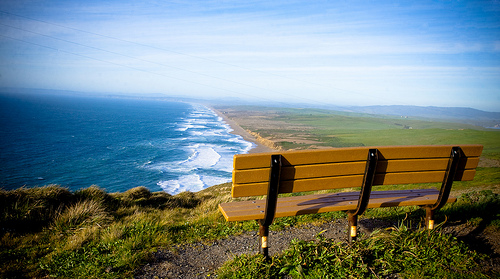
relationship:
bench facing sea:
[218, 146, 483, 259] [1, 87, 252, 196]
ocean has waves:
[0, 91, 251, 197] [190, 106, 249, 192]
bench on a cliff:
[218, 146, 483, 259] [0, 165, 496, 278]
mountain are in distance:
[326, 104, 498, 119] [1, 1, 496, 194]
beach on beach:
[212, 106, 274, 155] [212, 106, 274, 155]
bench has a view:
[218, 146, 483, 259] [1, 2, 497, 194]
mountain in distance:
[326, 104, 498, 119] [1, 1, 496, 194]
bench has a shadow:
[218, 146, 483, 259] [361, 200, 499, 259]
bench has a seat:
[218, 146, 483, 259] [217, 188, 454, 222]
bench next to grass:
[218, 146, 483, 259] [3, 177, 498, 279]